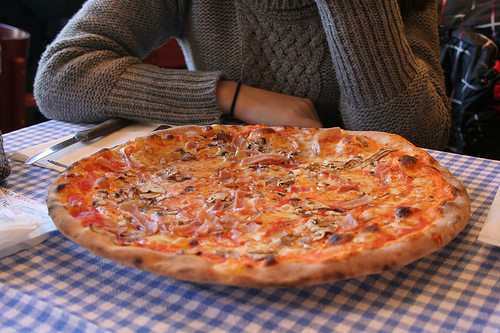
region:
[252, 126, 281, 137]
bubble in cheese on pizza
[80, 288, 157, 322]
blue and white checked table cloth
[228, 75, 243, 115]
black band around wrist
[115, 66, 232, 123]
long sleeve on grey sweater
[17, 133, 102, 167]
long silver knife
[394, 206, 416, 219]
burnt piece of cheese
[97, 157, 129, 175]
piece of meat on pizza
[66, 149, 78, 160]
white napkin on table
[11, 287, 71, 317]
wrinkle in table cloth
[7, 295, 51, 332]
Blue lines on a table cloth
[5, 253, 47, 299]
Blue lines on a table cloth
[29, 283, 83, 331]
Blue lines on a table cloth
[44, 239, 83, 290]
Blue lines on a table cloth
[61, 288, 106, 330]
Blue lines on a table cloth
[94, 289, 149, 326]
Blue lines on a table cloth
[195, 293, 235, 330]
Blue lines on a table cloth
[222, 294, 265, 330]
Blue lines on a table cloth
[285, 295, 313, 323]
vBlue lines on a table cloth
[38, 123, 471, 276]
This is a pizza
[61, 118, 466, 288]
None of the pizza has been eaten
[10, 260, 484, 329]
Blue and white tablecloth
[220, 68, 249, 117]
Woman has black tie around her wrist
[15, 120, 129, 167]
A knife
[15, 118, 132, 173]
The knife is resting on a napkin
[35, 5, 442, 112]
Woman is wearing a gray sweater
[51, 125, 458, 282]
The pizza is round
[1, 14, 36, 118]
A wooden chair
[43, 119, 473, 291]
Freshly baked pizza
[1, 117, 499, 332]
Blue and white checkered tablecloth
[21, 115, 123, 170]
Knife on a napkin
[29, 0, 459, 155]
Gray knit long-sleeved sweater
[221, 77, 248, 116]
Black band on a wrist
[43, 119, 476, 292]
Pizza on a blue and white tablecloth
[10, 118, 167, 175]
White napkins with a knife on top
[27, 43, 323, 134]
Elbow, arm and hand resting on a table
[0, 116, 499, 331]
Table with a blue and white tablecloth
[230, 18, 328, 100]
Knit cable pattern on front of sweater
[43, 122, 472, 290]
a baked uncut pizza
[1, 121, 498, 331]
a blue and white tablecloth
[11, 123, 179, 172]
a knife laying on a napkin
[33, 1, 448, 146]
a person wearing a gray sweater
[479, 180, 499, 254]
a white napkin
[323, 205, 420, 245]
black air pockets on the pizza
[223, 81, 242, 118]
a black band around a person's wrist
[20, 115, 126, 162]
a curved knife blade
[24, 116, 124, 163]
knife with a wooden handle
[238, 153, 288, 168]
a piece of ham on the pizza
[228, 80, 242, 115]
black band around a wrist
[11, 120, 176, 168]
white paper folded napkin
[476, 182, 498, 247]
white paper folded napkin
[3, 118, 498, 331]
blue and white checkered table cloth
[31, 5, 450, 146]
knit long sleeve sweater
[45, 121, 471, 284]
cooked cheese pizza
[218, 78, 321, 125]
hand of a person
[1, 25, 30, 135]
garbage can with a silver top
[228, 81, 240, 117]
black scrunchie on a person's arm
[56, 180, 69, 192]
dark spot on pizza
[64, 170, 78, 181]
dark spot on pizza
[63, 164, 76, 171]
dark spot on pizza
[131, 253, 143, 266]
dark spot on pizza